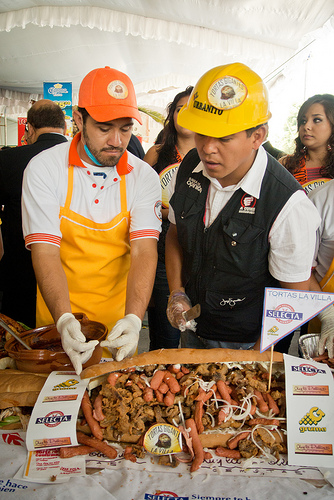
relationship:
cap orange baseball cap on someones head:
[78, 66, 144, 125] [68, 79, 154, 182]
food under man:
[0, 354, 333, 473] [21, 66, 163, 376]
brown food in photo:
[99, 353, 286, 364] [5, 171, 332, 457]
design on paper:
[290, 359, 325, 386] [283, 342, 332, 467]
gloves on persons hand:
[59, 314, 137, 355] [59, 247, 122, 296]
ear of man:
[255, 124, 267, 147] [172, 150, 252, 302]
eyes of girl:
[300, 115, 324, 122] [297, 157, 333, 179]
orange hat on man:
[79, 65, 141, 124] [69, 189, 129, 289]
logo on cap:
[102, 82, 132, 91] [78, 66, 144, 125]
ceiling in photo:
[0, 0, 334, 89] [12, 94, 325, 372]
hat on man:
[173, 85, 253, 136] [195, 147, 272, 248]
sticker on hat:
[202, 68, 249, 114] [177, 62, 273, 139]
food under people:
[51, 342, 273, 498] [30, 212, 284, 337]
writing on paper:
[288, 362, 328, 376] [283, 355, 332, 398]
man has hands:
[21, 66, 163, 376] [55, 310, 142, 379]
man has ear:
[158, 55, 321, 351] [253, 122, 267, 151]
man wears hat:
[158, 55, 321, 351] [173, 59, 276, 136]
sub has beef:
[77, 347, 285, 461] [91, 363, 286, 458]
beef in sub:
[91, 383, 163, 447] [74, 339, 285, 467]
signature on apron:
[218, 294, 243, 306] [162, 145, 301, 340]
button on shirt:
[82, 167, 119, 205] [15, 136, 169, 251]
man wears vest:
[158, 55, 321, 351] [167, 144, 303, 345]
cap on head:
[74, 60, 143, 129] [65, 60, 146, 171]